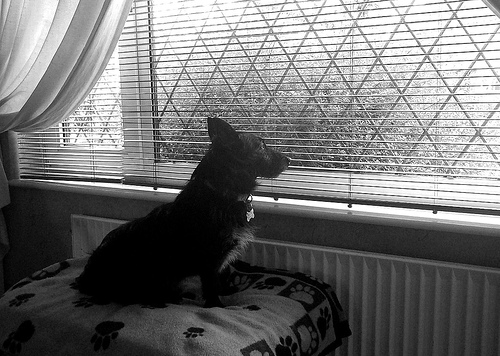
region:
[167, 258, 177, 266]
black fur on dog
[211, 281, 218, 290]
black fur on dog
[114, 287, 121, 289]
black fur on dog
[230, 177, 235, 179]
black fur on dog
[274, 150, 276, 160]
black fur on dog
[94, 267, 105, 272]
black fur on dog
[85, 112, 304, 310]
dog on the pillow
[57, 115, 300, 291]
dog on the pillow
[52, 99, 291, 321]
dog on the pillow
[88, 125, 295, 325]
dog on the pillow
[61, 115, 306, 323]
dog on the pillow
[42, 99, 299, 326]
dog on the pillow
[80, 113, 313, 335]
dog on the pillow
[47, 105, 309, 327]
dog on the pillow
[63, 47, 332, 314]
a dog in front a window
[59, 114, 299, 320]
the dog is color brown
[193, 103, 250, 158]
the ears of dog are pointy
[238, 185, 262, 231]
dog has a tag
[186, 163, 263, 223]
a collar with a tag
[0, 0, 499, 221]
window has blinds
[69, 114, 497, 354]
a heater below a window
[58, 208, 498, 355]
heater is color white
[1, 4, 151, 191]
a white curtain over a window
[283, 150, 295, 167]
nose of dog is black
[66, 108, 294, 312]
a small dog sits and looks out the window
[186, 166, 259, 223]
collar and tag around a dog's neck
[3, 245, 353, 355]
paw prints on a blanket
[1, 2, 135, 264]
curtain over a window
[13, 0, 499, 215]
white blinds over a window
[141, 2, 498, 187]
a shrub outside a window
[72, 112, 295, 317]
dog has dark colored fur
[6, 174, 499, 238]
shiny painted window ledge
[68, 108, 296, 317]
dog is staring out of the window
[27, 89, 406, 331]
dog looking out a window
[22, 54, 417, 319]
a dog looking out the window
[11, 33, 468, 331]
a dog looking out a window through the shade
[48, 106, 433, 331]
a small terrier mix looking out the window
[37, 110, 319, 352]
a black dog on a cushion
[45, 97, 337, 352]
a black dog with white markings on its chest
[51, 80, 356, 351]
a dog looking pensive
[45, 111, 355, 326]
a dog looking pensively out the window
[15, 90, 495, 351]
a dog staring wistfully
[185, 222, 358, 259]
THE DOG IS LOOKING OUTSIDE OF THE WINDOW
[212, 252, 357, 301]
THE DOG IS LOOKING OUTSIDE OF THE WINDOW